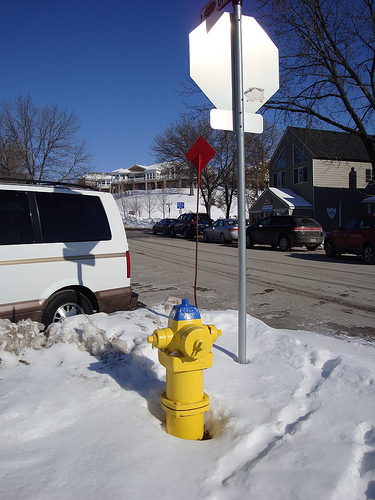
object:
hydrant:
[146, 299, 222, 441]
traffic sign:
[189, 3, 282, 131]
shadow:
[208, 339, 249, 363]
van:
[0, 179, 140, 335]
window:
[34, 197, 111, 244]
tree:
[245, 0, 375, 167]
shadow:
[85, 340, 167, 421]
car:
[243, 214, 321, 250]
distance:
[2, 0, 372, 235]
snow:
[0, 300, 375, 500]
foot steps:
[320, 348, 342, 378]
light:
[125, 250, 131, 279]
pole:
[231, 3, 248, 362]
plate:
[310, 237, 318, 248]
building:
[265, 127, 374, 228]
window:
[347, 169, 357, 194]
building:
[78, 161, 264, 199]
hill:
[117, 188, 259, 232]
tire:
[38, 288, 98, 334]